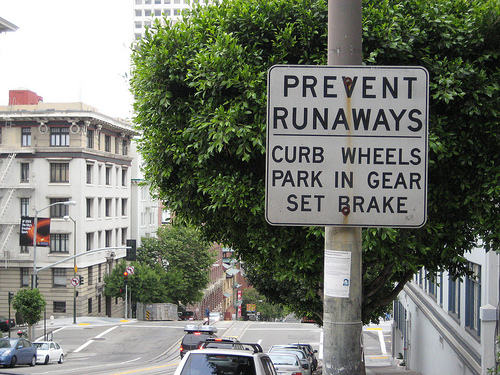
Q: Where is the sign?
A: On a pole.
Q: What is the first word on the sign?
A: Prevent.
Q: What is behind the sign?
A: A tree.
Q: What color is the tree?
A: Green.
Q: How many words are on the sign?
A: Nine.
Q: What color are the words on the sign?
A: Black.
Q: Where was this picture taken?
A: The city.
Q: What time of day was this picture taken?
A: Daytime.